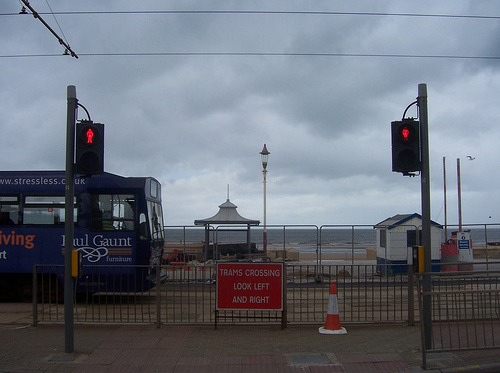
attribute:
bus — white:
[1, 165, 162, 305]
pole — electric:
[414, 81, 440, 357]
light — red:
[77, 115, 105, 151]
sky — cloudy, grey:
[205, 79, 301, 112]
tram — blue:
[14, 172, 163, 290]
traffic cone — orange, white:
[319, 275, 347, 335]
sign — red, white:
[394, 124, 418, 141]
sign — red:
[218, 260, 280, 315]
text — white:
[217, 265, 283, 281]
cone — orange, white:
[328, 281, 338, 293]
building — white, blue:
[367, 211, 418, 277]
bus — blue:
[83, 181, 159, 285]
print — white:
[77, 233, 133, 248]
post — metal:
[153, 264, 167, 274]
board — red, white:
[459, 247, 474, 263]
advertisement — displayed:
[7, 173, 68, 190]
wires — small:
[185, 5, 249, 20]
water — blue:
[290, 240, 312, 253]